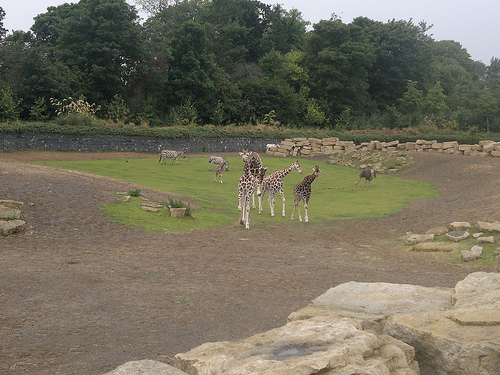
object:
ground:
[0, 239, 299, 307]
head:
[312, 165, 323, 176]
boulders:
[335, 140, 353, 144]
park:
[16, 87, 471, 339]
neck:
[276, 165, 293, 178]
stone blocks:
[367, 141, 375, 149]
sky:
[298, 0, 500, 59]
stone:
[322, 138, 338, 146]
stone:
[264, 140, 275, 148]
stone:
[443, 142, 458, 151]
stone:
[386, 140, 399, 147]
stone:
[479, 140, 492, 146]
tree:
[27, 0, 145, 128]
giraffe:
[237, 167, 266, 229]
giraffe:
[259, 160, 303, 217]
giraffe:
[293, 165, 322, 222]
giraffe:
[238, 149, 262, 174]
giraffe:
[214, 158, 229, 183]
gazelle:
[355, 169, 375, 188]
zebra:
[160, 150, 186, 165]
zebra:
[209, 156, 229, 170]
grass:
[28, 155, 434, 236]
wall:
[1, 130, 284, 153]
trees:
[241, 6, 317, 137]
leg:
[279, 188, 286, 217]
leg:
[272, 191, 275, 216]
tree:
[165, 0, 217, 126]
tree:
[303, 19, 366, 127]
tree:
[428, 36, 498, 131]